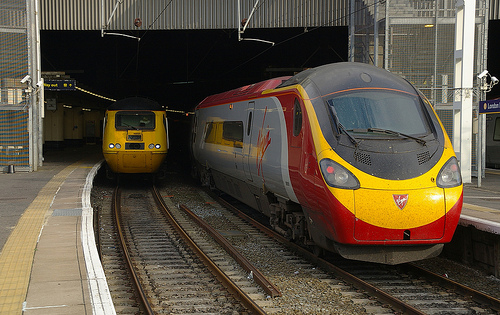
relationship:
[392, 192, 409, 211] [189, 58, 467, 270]
logo on train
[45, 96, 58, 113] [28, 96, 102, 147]
sign hanging from wall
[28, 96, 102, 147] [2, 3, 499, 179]
wall on train station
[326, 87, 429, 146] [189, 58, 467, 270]
window on train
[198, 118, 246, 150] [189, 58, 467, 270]
window on train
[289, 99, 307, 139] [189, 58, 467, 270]
window on train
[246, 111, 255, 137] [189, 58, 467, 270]
window on train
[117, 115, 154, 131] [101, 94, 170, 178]
window on train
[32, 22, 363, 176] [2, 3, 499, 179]
entrance to train station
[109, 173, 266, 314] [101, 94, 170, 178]
train tracks are for train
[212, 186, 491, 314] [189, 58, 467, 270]
train tracks are for train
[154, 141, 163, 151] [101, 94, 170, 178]
light on train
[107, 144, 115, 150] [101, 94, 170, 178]
light on train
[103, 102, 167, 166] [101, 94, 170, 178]
front of train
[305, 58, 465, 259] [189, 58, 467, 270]
front of train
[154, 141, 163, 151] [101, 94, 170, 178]
light on front of train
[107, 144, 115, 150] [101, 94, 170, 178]
light on front of train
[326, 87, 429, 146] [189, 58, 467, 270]
window on a train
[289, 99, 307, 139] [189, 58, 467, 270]
window on a train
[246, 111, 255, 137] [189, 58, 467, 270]
window on a train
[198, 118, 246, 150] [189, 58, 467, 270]
window on a train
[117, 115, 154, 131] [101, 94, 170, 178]
window on a train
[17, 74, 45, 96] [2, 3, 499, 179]
camera by a train station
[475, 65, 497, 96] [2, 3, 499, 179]
camera by a train station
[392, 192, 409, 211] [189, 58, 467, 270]
logo on front of train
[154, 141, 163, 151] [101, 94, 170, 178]
light on a train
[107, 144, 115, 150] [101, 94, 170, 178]
light on a train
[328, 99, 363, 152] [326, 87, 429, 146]
windshield wiper on window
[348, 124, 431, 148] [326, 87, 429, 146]
windshield wiper on window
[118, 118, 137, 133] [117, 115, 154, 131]
windshield wiper on window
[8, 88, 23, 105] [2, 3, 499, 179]
window in train station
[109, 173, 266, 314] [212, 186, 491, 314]
train tracks side by side to train tracks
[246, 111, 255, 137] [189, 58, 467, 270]
window on side of train